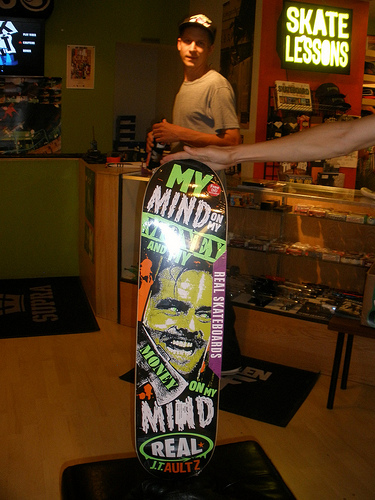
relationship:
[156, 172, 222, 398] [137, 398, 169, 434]
board has a letter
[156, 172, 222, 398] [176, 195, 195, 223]
board has a letter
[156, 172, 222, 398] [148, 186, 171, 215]
board has a letter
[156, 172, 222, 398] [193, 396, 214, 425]
board has a letter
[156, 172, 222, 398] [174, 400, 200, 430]
board has a letter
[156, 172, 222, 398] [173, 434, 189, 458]
board has a letter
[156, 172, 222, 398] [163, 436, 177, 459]
board has a letter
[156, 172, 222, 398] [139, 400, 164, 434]
board has a letter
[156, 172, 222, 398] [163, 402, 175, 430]
board has a letter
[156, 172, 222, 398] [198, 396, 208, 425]
board has a letter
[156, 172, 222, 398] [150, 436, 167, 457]
board has a letter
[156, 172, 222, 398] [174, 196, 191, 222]
board has a letter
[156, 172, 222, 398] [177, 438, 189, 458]
board has a letter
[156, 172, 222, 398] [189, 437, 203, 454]
board has a letter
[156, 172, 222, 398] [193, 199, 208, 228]
board has a letter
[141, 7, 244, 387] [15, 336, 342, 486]
man on deck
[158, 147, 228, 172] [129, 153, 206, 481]
hand on board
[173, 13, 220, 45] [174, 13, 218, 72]
hat on head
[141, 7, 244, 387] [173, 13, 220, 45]
man with hat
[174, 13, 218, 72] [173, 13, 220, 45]
head with hat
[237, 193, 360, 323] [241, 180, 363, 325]
case on counter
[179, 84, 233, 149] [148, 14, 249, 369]
shirt on man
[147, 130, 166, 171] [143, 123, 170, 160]
bottle in hand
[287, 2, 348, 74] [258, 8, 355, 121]
sign on wall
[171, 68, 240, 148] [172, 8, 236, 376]
shirt on man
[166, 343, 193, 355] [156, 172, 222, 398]
teeth on board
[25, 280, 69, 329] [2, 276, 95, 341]
letters on mat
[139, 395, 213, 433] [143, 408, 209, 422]
word in text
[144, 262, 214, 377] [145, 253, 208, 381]
face on image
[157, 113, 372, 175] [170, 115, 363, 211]
arm on man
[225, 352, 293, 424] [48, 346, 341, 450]
rug on floor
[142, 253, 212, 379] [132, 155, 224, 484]
jack-nicholson's face on skateboard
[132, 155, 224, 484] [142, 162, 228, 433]
skateboard with words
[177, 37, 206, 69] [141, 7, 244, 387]
face on man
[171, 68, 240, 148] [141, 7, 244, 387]
shirt on man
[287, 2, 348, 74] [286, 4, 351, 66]
sign says skate lessons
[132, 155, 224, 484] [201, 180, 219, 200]
skateboard with sticker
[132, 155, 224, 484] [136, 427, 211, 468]
skateboard with sticker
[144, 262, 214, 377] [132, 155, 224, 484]
face on skateboard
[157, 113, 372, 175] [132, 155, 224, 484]
arm holding skateboard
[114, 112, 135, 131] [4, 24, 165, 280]
shelf in back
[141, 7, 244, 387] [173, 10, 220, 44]
man wearing cap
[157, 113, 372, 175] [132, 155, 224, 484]
arm holding up skateboard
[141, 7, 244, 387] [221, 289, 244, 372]
man wearing pants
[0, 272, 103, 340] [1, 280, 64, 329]
mat with logo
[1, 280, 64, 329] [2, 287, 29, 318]
logo has crown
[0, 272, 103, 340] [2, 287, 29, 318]
mat with crown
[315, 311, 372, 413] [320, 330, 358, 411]
bench with legs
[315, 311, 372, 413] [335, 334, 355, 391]
bench with leg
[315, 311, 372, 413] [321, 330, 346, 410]
bench with leg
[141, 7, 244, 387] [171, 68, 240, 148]
man wearing shirt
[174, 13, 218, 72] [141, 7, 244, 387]
head of man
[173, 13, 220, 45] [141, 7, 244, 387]
hat of man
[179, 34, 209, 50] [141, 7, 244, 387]
eyes of man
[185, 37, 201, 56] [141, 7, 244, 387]
nose of man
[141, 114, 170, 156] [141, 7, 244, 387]
hands of man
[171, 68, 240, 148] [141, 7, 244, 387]
shirt of man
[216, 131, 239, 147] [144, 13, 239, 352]
elbow of man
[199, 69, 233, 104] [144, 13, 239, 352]
shoulder of man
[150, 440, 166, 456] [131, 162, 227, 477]
letter on board